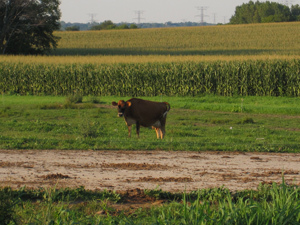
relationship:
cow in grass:
[111, 98, 171, 140] [26, 95, 93, 142]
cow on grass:
[111, 98, 171, 140] [26, 95, 93, 142]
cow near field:
[111, 98, 171, 140] [104, 29, 213, 77]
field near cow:
[104, 29, 213, 77] [111, 98, 171, 140]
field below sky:
[104, 29, 213, 77] [59, 0, 226, 23]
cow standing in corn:
[111, 98, 171, 140] [0, 22, 299, 95]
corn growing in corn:
[0, 22, 299, 95] [0, 22, 299, 95]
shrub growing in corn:
[65, 88, 84, 103] [0, 22, 299, 95]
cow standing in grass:
[111, 96, 172, 138] [1, 93, 297, 223]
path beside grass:
[1, 146, 298, 191] [4, 94, 299, 151]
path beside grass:
[1, 146, 298, 191] [1, 186, 296, 223]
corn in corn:
[3, 20, 299, 93] [0, 22, 299, 95]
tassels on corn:
[0, 21, 299, 73] [3, 20, 299, 93]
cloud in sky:
[47, 1, 298, 26] [35, 0, 297, 25]